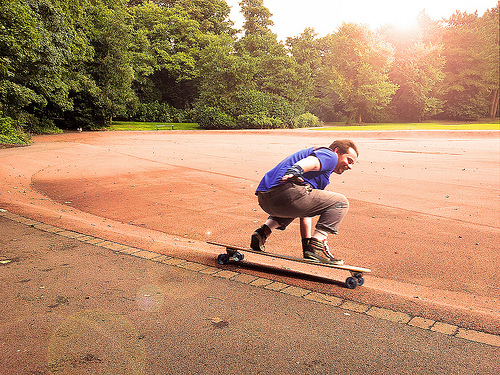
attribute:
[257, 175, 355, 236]
pants — tan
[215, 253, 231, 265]
wheel — four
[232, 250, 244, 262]
wheel — four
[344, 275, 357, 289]
wheel — four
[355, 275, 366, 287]
wheel — four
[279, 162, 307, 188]
fingerless gloves — black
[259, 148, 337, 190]
shirt — BLUE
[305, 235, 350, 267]
boot — big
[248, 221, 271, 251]
boot — big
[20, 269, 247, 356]
pavement — black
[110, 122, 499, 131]
lawn — green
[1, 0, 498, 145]
forest — green trees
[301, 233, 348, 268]
boot — BIG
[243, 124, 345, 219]
purple shirt — short sleeve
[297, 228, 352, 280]
boot — BIG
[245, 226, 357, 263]
boot — big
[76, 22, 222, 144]
trees — GREEN, TALL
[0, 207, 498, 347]
bricks — bordering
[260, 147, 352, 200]
shirt — blue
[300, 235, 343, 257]
boot — BIG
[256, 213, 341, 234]
cuffs — rolled up